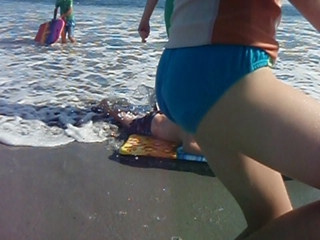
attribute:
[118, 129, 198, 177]
floatation device — colorful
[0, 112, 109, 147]
foam — white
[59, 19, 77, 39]
swimming trunks — black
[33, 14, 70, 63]
board — pink, multicolored